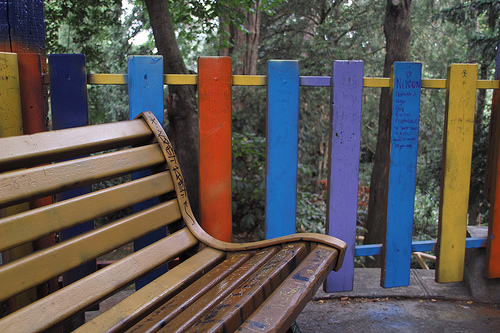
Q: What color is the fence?
A: Rainbow.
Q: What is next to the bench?
A: A fence.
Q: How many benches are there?
A: One.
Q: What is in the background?
A: Trees.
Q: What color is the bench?
A: Brown.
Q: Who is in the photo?
A: No one.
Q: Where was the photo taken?
A: In a park.